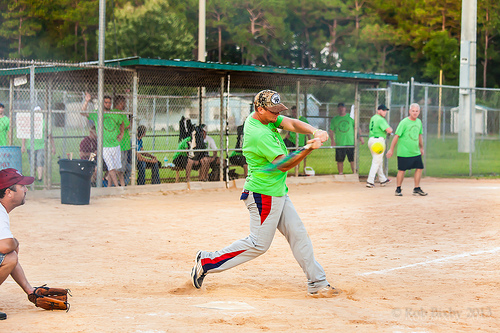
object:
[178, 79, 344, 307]
man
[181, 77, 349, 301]
pants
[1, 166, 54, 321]
catcher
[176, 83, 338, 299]
batter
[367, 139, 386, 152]
softball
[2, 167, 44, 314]
man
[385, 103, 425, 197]
man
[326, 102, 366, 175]
man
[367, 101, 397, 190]
man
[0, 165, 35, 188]
red hat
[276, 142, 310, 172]
bat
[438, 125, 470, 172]
ground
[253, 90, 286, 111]
baseball cap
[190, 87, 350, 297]
man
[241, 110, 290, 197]
green shirt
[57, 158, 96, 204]
trash can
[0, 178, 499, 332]
dirt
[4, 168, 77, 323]
catcher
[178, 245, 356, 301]
cleats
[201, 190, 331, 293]
pants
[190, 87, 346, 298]
batter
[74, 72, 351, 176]
dugout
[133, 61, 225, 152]
dugout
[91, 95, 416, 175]
team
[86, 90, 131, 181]
player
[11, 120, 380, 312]
game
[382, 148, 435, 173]
shorts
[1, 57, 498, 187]
fence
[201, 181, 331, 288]
pants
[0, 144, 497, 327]
field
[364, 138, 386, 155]
baseball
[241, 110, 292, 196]
shirt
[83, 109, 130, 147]
shirt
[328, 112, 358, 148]
shirt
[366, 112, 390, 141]
shirt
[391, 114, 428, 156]
shirt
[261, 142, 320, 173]
bat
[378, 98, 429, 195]
man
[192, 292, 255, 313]
home plate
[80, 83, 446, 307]
team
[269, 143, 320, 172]
bat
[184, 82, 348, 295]
player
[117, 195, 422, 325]
dirt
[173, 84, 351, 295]
man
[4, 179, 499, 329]
baseball field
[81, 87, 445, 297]
team